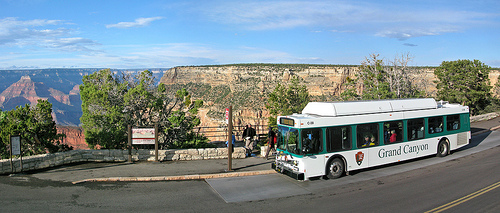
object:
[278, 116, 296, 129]
destination window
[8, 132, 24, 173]
sign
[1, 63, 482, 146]
grand canyon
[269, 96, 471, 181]
bus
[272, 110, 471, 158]
trim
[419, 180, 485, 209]
double line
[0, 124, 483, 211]
road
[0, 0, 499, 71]
sky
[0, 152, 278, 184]
sidewalk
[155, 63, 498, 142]
plateau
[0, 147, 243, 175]
wall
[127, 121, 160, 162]
sign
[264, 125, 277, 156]
man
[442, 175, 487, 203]
lines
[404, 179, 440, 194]
street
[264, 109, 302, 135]
window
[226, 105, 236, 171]
pole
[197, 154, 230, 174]
sidewalk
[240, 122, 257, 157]
man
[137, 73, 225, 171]
grand canyon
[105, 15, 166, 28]
clouds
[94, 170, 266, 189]
curb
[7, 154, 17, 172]
poles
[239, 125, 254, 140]
jacket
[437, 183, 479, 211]
lines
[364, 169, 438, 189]
road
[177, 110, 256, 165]
barrier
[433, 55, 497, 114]
tree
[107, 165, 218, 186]
curb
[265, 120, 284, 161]
sleeves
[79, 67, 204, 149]
tree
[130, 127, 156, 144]
sign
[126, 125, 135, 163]
poles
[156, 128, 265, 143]
fence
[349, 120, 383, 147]
window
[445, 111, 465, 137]
window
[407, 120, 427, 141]
window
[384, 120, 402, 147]
window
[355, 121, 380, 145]
window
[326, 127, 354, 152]
window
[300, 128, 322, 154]
window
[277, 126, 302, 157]
window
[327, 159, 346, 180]
wheel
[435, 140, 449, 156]
wheel